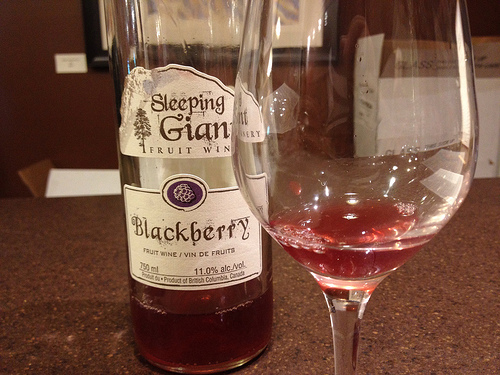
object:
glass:
[230, 0, 479, 375]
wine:
[266, 198, 438, 282]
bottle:
[102, 0, 278, 375]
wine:
[127, 278, 273, 375]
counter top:
[0, 175, 500, 375]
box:
[351, 33, 499, 180]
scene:
[0, 0, 500, 375]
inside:
[0, 0, 500, 375]